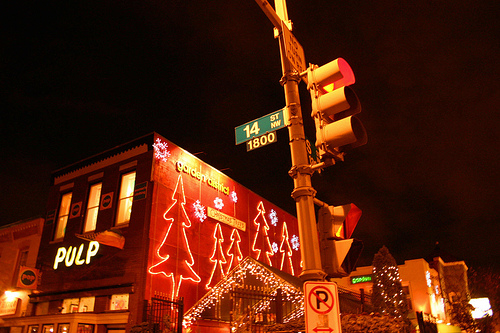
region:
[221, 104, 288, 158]
A green street sign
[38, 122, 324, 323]
A red building is in the background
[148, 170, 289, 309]
A neon light outline of pine trees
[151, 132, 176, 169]
A snowflake is on the building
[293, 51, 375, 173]
Traffic light is on the red light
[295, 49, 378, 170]
Traffic light is yellow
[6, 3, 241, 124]
The sky is dark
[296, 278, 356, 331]
A white traffic sign is in the foreground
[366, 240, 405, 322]
Tree has lights on it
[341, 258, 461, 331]
A tan colored building is in the background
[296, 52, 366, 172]
a three way stop light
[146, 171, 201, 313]
a neon christmas tree light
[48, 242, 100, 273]
a lit business sign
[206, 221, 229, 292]
a neon lit christmas tree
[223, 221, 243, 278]
a neon lit christmas tree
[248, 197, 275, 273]
a neon lit christmas tree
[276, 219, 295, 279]
a neon lit christmas tree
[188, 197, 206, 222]
a white lit neon snowflake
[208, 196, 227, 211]
a white lit neon snowflake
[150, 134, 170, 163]
a white lit neon snowflake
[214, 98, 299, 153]
a street sign with a number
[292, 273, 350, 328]
a no parking sign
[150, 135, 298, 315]
lights decorating a building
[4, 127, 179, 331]
a business on the street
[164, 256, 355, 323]
lights decorating an awning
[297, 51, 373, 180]
a streetlight post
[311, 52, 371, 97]
a red light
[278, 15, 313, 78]
a white sign with black writing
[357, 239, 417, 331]
a green tree with lights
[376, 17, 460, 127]
a black night sky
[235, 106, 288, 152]
A sign on the post.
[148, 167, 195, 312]
A neon tree light.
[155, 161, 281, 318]
Neon lights on the building.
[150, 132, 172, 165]
A neon snow flake.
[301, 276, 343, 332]
A no parking sign.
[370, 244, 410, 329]
A tree with lights.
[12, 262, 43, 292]
A sign for the building.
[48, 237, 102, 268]
The name of the store.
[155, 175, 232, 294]
The building is red.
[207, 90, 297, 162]
street sign with a number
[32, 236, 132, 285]
the name of a business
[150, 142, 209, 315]
christmas tree lights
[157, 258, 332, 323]
icicle lights hanging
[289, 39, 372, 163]
a traffic light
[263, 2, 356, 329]
traffic light pole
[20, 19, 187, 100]
a dark black sky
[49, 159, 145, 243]
windows of the building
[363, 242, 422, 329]
a tree with lights on it